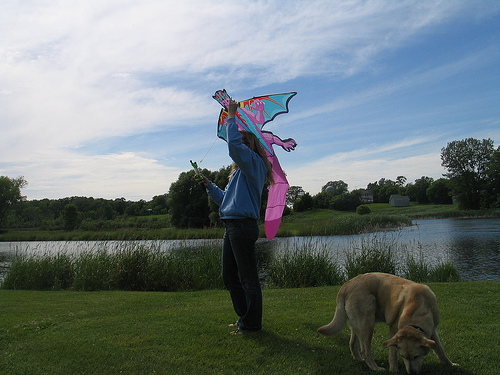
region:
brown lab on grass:
[304, 264, 454, 369]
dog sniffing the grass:
[310, 258, 458, 374]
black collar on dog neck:
[390, 323, 440, 333]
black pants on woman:
[220, 223, 265, 324]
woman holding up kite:
[158, 70, 319, 350]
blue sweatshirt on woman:
[199, 118, 274, 218]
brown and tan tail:
[316, 286, 351, 333]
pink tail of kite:
[263, 155, 290, 238]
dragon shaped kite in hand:
[207, 75, 314, 234]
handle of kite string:
[185, 156, 207, 182]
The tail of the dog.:
[321, 293, 346, 340]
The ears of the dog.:
[383, 337, 435, 349]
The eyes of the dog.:
[395, 355, 425, 360]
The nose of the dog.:
[406, 371, 417, 373]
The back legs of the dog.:
[347, 312, 382, 373]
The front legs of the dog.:
[386, 329, 453, 374]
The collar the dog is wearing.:
[410, 323, 433, 335]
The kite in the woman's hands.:
[217, 87, 292, 242]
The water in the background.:
[6, 213, 498, 288]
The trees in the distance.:
[2, 171, 492, 226]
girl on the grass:
[160, 75, 322, 336]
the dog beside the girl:
[309, 256, 453, 373]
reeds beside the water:
[21, 240, 219, 293]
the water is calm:
[391, 225, 498, 280]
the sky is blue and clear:
[395, 45, 480, 132]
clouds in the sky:
[7, 6, 139, 136]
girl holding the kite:
[187, 104, 296, 334]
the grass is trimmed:
[10, 294, 226, 371]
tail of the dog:
[317, 275, 345, 340]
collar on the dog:
[402, 319, 434, 347]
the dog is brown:
[332, 276, 449, 373]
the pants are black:
[214, 230, 271, 334]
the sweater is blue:
[210, 150, 273, 211]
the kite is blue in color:
[205, 87, 289, 151]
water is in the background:
[391, 213, 488, 258]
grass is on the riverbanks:
[44, 235, 191, 276]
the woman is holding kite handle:
[183, 158, 217, 191]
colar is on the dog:
[406, 318, 426, 334]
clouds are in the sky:
[42, 25, 77, 103]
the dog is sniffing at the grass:
[311, 256, 460, 370]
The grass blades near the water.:
[4, 240, 463, 295]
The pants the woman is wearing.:
[216, 220, 261, 335]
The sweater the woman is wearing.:
[200, 118, 272, 219]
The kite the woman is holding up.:
[202, 83, 298, 240]